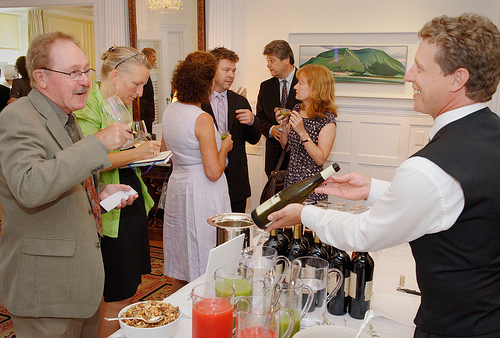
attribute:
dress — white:
[160, 98, 234, 283]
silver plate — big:
[207, 210, 254, 262]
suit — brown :
[3, 90, 135, 302]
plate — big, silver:
[207, 210, 258, 294]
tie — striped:
[206, 101, 238, 138]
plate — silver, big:
[208, 212, 257, 228]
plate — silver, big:
[213, 141, 497, 328]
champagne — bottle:
[247, 161, 341, 237]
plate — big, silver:
[175, 296, 194, 332]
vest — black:
[405, 106, 498, 336]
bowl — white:
[115, 294, 188, 333]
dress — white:
[155, 106, 232, 277]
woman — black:
[274, 62, 341, 205]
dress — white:
[284, 102, 339, 202]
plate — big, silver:
[190, 196, 269, 256]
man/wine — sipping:
[2, 31, 159, 331]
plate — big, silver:
[204, 212, 257, 234]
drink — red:
[189, 298, 234, 336]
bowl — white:
[116, 297, 181, 337]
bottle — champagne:
[283, 171, 333, 206]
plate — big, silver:
[206, 205, 261, 262]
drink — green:
[216, 279, 246, 294]